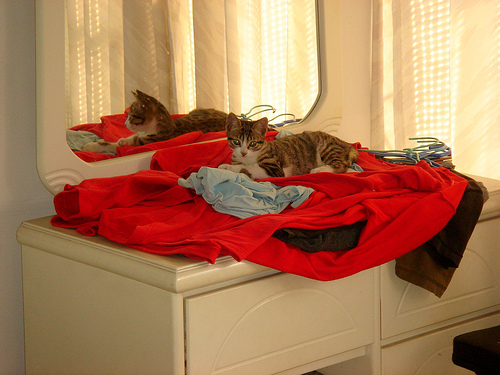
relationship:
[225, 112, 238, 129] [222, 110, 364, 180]
ear of cat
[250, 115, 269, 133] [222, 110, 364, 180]
ear of cat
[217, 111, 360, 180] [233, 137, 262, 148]
cat has eyes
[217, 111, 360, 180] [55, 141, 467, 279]
cat on blanket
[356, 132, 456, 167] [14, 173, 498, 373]
hangers are on dresser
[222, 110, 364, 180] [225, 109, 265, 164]
cat has cat head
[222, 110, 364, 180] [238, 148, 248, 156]
cat has nose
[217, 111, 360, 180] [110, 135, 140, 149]
cat has paw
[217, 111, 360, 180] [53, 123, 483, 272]
cat on blanket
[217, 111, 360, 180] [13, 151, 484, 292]
cat lying on counter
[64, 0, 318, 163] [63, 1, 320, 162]
reflection seen in mirror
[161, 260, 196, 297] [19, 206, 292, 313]
corner of counter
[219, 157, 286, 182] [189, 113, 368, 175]
leg on cat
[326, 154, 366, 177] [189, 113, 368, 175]
leg on cat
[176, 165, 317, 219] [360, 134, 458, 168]
cloth are on hangers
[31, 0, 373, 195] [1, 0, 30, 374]
frame around wall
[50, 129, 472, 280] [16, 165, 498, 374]
fabric on counter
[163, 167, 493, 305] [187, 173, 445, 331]
fabric over counter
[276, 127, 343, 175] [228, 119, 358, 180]
body of cat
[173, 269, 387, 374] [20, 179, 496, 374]
drawer of cabinet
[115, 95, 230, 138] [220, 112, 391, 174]
reflection of cat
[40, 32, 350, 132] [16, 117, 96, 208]
mirror in frame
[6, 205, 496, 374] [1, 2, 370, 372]
dresser against wall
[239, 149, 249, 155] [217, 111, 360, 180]
nose of cat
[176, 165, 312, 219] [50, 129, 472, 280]
cloth on fabric